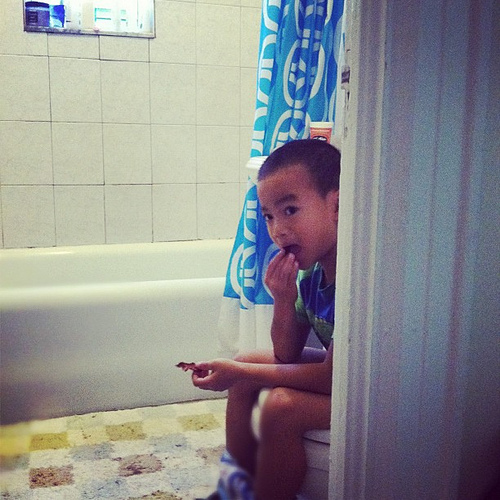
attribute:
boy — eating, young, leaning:
[191, 139, 340, 499]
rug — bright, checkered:
[1, 396, 229, 499]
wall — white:
[0, 1, 265, 247]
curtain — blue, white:
[217, 1, 346, 364]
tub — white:
[2, 237, 240, 426]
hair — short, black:
[256, 138, 346, 199]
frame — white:
[344, 0, 468, 499]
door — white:
[327, 2, 391, 499]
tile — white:
[98, 58, 154, 126]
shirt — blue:
[291, 263, 337, 350]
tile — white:
[50, 119, 108, 187]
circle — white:
[282, 37, 325, 108]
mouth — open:
[280, 242, 305, 259]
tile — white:
[100, 120, 158, 187]